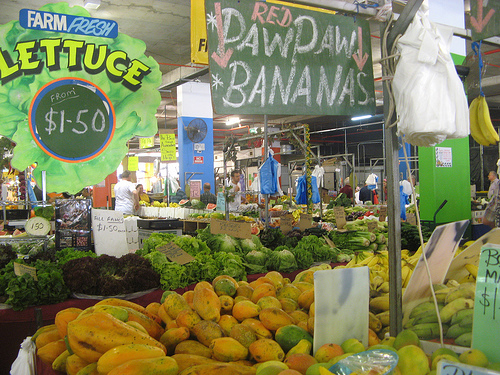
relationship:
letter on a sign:
[61, 30, 81, 72] [8, 6, 162, 199]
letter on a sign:
[124, 62, 150, 86] [8, 6, 162, 199]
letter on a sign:
[61, 38, 81, 71] [8, 6, 162, 199]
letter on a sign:
[88, 44, 104, 71] [8, 6, 162, 199]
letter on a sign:
[106, 44, 125, 79] [8, 6, 162, 199]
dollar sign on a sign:
[43, 110, 58, 130] [8, 6, 162, 199]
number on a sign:
[68, 105, 89, 141] [8, 9, 151, 196]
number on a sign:
[72, 109, 89, 135] [9, 14, 158, 190]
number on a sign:
[88, 106, 109, 133] [8, 6, 162, 199]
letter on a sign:
[225, 64, 253, 107] [205, 3, 381, 115]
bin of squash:
[46, 269, 463, 373] [71, 301, 288, 363]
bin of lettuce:
[11, 234, 161, 312] [65, 250, 155, 289]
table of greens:
[118, 196, 378, 262] [105, 224, 324, 277]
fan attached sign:
[183, 115, 212, 142] [170, 80, 220, 193]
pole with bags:
[368, 16, 418, 336] [389, 10, 474, 142]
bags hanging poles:
[396, 10, 473, 149] [371, 30, 414, 331]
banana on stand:
[469, 96, 492, 147] [369, 15, 481, 66]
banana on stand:
[469, 96, 492, 147] [391, 16, 478, 52]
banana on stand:
[469, 96, 492, 147] [443, 20, 483, 47]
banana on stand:
[469, 96, 492, 147] [448, 25, 481, 45]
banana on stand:
[462, 96, 483, 150] [446, 26, 484, 58]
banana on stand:
[456, 82, 483, 150] [449, 25, 484, 42]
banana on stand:
[469, 96, 492, 147] [442, 28, 484, 57]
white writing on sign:
[242, 101, 284, 141] [214, 53, 367, 88]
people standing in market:
[26, 132, 380, 278] [78, 183, 403, 375]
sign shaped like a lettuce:
[18, 63, 125, 213] [31, 114, 98, 204]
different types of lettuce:
[54, 208, 291, 339] [8, 186, 304, 283]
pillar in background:
[171, 77, 221, 176] [82, 99, 451, 293]